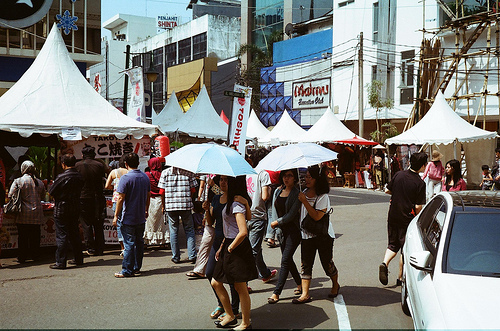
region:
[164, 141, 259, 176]
a light blue canopy of an umbrella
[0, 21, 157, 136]
a white tent canopy of a booth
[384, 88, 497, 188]
a tent booth with sides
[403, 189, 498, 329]
a car parked on the side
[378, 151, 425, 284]
a man wearing black short and shirt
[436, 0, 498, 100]
a wooden fire escape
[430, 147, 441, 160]
a lady wearing a wide brimmed hat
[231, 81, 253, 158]
advertising banner hanging from a building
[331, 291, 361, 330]
white painted line designating a parking space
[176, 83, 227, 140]
a blue canopy tent booth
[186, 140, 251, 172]
the umbreelas are white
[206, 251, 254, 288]
the skirt is black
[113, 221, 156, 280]
the jeans are blue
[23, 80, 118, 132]
the tent is white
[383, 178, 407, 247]
the clothing is black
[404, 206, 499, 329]
the car is white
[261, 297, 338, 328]
umbrella shadow is on the ground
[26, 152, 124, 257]
the people are about to buy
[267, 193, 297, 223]
she has a grey sweater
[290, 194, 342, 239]
her top is white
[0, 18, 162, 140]
A white tent covering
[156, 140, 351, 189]
A pair of umbrellas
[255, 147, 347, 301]
Two woman under an umbrella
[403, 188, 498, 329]
A parked white car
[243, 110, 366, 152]
Three tent coverings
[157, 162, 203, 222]
a man with a white and black checkered shirt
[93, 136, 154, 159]
a sign with pictures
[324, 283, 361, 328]
A white street marking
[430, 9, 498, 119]
a scaffold against a building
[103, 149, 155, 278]
a man with a blue shirt and blue jeans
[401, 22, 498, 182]
the scaffolding near the building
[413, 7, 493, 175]
the scaffolding is made of bamboo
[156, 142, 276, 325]
two women under an umbrella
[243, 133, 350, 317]
two women under an umbrella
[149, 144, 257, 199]
the umbrella is white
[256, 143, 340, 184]
the umbrella is white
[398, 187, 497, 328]
a car in the street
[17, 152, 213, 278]
a crowd of people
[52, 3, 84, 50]
a snowflake on the building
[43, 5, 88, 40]
the snowflake is blue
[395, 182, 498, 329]
A car is in the corner.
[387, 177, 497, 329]
The car is white.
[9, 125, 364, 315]
A lot of people are on the street.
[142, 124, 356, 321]
People are carrying umbrellas.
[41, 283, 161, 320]
The ground is gray.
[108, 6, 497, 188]
Buildings are in the background.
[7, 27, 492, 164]
A lot of tents are in the picture.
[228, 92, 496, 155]
The tents are white.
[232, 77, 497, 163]
The tents are pointy.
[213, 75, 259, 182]
A banner.